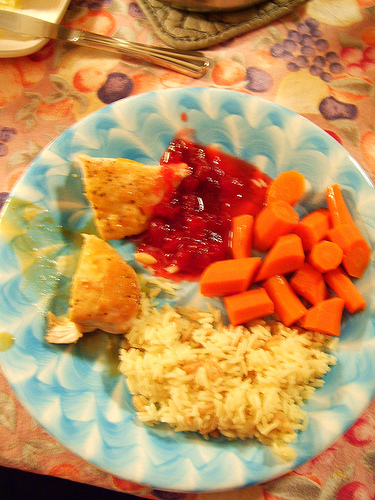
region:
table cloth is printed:
[314, 477, 329, 497]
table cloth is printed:
[325, 470, 333, 487]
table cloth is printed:
[313, 474, 322, 484]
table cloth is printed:
[328, 475, 334, 499]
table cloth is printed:
[335, 471, 343, 481]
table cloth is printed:
[318, 470, 331, 498]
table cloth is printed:
[335, 465, 345, 494]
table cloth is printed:
[314, 475, 320, 492]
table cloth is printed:
[326, 471, 336, 497]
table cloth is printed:
[322, 473, 329, 494]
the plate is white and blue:
[162, 465, 173, 488]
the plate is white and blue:
[187, 466, 205, 490]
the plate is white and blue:
[206, 466, 214, 484]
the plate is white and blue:
[175, 471, 190, 497]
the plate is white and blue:
[177, 457, 196, 491]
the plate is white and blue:
[185, 488, 191, 496]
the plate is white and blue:
[178, 467, 185, 487]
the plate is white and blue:
[192, 471, 197, 485]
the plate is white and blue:
[173, 458, 188, 486]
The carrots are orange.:
[238, 188, 352, 319]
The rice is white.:
[134, 310, 301, 433]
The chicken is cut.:
[64, 145, 147, 340]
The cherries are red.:
[126, 123, 273, 266]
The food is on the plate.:
[23, 109, 361, 459]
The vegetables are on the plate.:
[212, 174, 373, 335]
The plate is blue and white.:
[3, 77, 373, 447]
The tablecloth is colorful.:
[13, 65, 80, 131]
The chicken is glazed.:
[28, 144, 167, 340]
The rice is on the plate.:
[93, 256, 358, 463]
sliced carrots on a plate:
[223, 166, 374, 340]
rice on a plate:
[134, 316, 309, 423]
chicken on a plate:
[48, 153, 184, 334]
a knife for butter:
[10, 9, 208, 85]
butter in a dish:
[3, 2, 67, 21]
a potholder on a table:
[135, 3, 341, 43]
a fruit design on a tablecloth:
[277, 21, 371, 116]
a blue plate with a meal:
[16, 80, 366, 493]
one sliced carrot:
[201, 252, 261, 299]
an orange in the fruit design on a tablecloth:
[69, 66, 110, 92]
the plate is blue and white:
[222, 472, 234, 498]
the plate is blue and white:
[208, 474, 218, 487]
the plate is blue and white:
[203, 481, 215, 498]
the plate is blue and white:
[205, 473, 216, 492]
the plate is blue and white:
[213, 475, 225, 491]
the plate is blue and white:
[213, 484, 221, 496]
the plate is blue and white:
[213, 488, 219, 497]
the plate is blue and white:
[197, 476, 207, 496]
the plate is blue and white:
[186, 460, 202, 478]